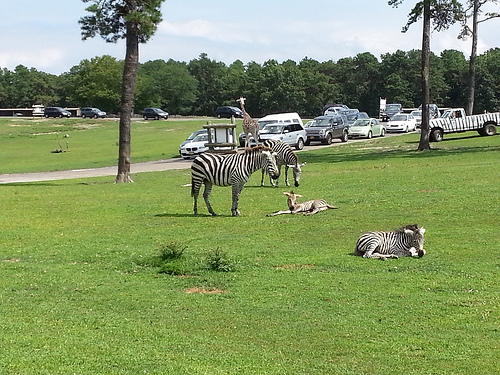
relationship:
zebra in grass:
[187, 143, 279, 220] [45, 241, 372, 356]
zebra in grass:
[352, 223, 430, 261] [45, 241, 372, 356]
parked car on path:
[387, 110, 417, 134] [0, 108, 437, 192]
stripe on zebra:
[204, 153, 212, 179] [183, 142, 285, 218]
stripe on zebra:
[200, 153, 212, 181] [189, 147, 277, 216]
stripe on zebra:
[357, 234, 369, 251] [352, 223, 425, 258]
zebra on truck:
[348, 216, 438, 268] [419, 103, 499, 148]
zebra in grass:
[352, 223, 430, 261] [250, 259, 499, 374]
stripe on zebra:
[210, 149, 226, 166] [183, 142, 285, 218]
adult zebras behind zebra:
[356, 226, 469, 265] [260, 189, 340, 219]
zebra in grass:
[156, 143, 333, 244] [205, 234, 367, 331]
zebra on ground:
[352, 223, 430, 261] [1, 105, 499, 374]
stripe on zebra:
[190, 154, 206, 183] [187, 157, 270, 197]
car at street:
[252, 121, 310, 151] [4, 109, 456, 185]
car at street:
[179, 128, 238, 158] [4, 109, 456, 185]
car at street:
[308, 114, 348, 141] [4, 109, 456, 185]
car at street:
[382, 111, 419, 132] [4, 109, 456, 185]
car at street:
[344, 117, 389, 141] [4, 109, 456, 185]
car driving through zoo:
[252, 121, 310, 151] [1, 109, 498, 371]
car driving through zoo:
[301, 114, 350, 145] [1, 109, 498, 371]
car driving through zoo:
[344, 117, 380, 136] [1, 109, 498, 371]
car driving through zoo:
[179, 128, 229, 154] [1, 109, 498, 371]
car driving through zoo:
[382, 111, 412, 132] [1, 109, 498, 371]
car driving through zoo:
[42, 106, 67, 119] [1, 109, 498, 371]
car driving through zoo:
[77, 105, 105, 117] [1, 109, 498, 371]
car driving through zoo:
[135, 106, 167, 122] [1, 109, 498, 371]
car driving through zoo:
[210, 106, 243, 118] [1, 109, 498, 371]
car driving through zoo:
[376, 102, 401, 114] [1, 109, 498, 371]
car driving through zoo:
[323, 105, 345, 115] [1, 109, 498, 371]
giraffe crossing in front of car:
[228, 89, 270, 154] [252, 121, 310, 151]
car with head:
[252, 121, 310, 151] [233, 89, 245, 109]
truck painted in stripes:
[425, 109, 498, 148] [426, 113, 496, 134]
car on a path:
[179, 128, 238, 158] [0, 115, 420, 183]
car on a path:
[252, 121, 310, 151] [2, 160, 122, 180]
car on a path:
[344, 117, 389, 141] [1, 122, 425, 187]